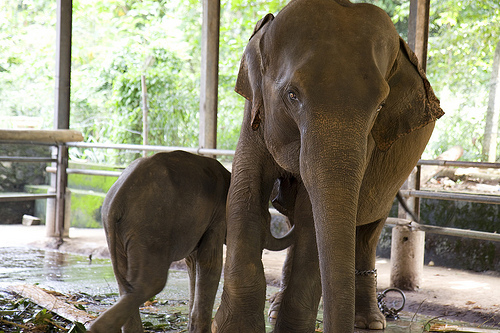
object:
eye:
[284, 88, 303, 104]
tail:
[103, 205, 139, 296]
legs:
[110, 248, 148, 332]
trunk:
[296, 121, 372, 331]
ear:
[230, 17, 278, 132]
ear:
[365, 36, 447, 155]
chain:
[349, 268, 408, 321]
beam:
[57, 0, 70, 135]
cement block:
[390, 222, 428, 294]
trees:
[0, 0, 498, 273]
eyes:
[372, 104, 389, 114]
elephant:
[73, 149, 244, 332]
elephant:
[206, 0, 447, 332]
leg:
[340, 216, 388, 331]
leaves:
[9, 297, 30, 307]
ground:
[0, 224, 499, 332]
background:
[0, 0, 499, 332]